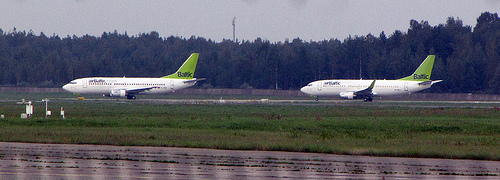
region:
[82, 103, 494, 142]
green patch of grass along runway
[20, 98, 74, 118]
cluster of white devices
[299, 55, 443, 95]
airplane sitting on runway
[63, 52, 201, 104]
second airplane sitting on runway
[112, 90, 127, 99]
engine used to power airplane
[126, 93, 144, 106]
wheels used for landing and takeoffs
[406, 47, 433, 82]
green tail with company name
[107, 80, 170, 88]
windows for passengers to see from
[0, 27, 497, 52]
forest of trees in background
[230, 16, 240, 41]
incredibly tall structure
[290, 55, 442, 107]
a large white airplane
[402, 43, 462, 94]
the yellow tail of an airplane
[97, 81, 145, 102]
the wing of an airplane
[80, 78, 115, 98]
the windows of an airplane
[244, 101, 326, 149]
fresh green cut grass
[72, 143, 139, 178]
the large grey asphalt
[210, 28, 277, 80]
a bundle of large green trees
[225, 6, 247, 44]
a large tall flag pole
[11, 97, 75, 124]
small white warning signs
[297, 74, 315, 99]
the nose of the airplane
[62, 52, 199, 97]
a plane is on the runway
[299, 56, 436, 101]
a plane is on the runway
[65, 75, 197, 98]
the plane is white in color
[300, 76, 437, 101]
the plane is white in color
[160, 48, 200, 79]
the train has a green tail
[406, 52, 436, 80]
the train has a green tail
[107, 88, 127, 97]
an engine is under the wing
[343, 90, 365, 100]
an engine is under the wing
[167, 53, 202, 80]
the tail is green in color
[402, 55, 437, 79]
the tail is green in color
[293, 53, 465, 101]
white airplane with green tail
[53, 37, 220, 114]
white airplane with green tail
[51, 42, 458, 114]
two white airplanes with green tails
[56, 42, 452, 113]
two airplanes on landing strip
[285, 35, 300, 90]
tall green leafy tree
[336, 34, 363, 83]
tall green leafy tree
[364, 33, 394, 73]
tall green leafy tree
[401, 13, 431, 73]
tall green leafy tree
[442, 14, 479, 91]
tall green leafy tree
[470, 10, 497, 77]
tall green leafy tree